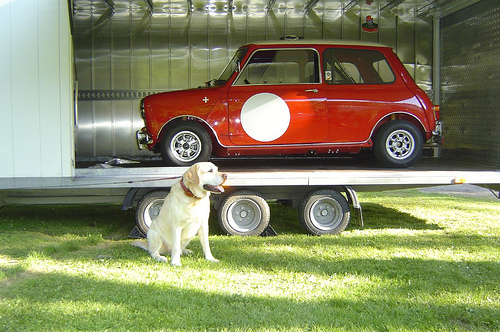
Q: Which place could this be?
A: It is a field.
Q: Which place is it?
A: It is a field.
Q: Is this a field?
A: Yes, it is a field.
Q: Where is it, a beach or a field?
A: It is a field.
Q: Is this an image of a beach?
A: No, the picture is showing a field.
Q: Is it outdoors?
A: Yes, it is outdoors.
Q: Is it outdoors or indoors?
A: It is outdoors.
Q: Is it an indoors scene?
A: No, it is outdoors.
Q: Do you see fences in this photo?
A: No, there are no fences.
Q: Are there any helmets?
A: No, there are no helmets.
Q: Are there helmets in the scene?
A: No, there are no helmets.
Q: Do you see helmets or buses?
A: No, there are no helmets or buses.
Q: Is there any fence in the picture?
A: No, there are no fences.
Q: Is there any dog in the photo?
A: Yes, there is a dog.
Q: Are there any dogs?
A: Yes, there is a dog.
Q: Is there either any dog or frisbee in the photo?
A: Yes, there is a dog.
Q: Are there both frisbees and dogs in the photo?
A: No, there is a dog but no frisbees.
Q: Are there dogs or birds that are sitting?
A: Yes, the dog is sitting.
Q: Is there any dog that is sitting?
A: Yes, there is a dog that is sitting.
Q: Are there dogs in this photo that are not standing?
A: Yes, there is a dog that is sitting.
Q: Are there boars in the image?
A: No, there are no boars.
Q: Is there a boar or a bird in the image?
A: No, there are no boars or birds.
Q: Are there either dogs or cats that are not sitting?
A: No, there is a dog but it is sitting.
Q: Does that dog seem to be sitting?
A: Yes, the dog is sitting.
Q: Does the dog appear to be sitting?
A: Yes, the dog is sitting.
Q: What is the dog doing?
A: The dog is sitting.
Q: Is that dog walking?
A: No, the dog is sitting.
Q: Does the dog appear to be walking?
A: No, the dog is sitting.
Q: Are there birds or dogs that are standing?
A: No, there is a dog but it is sitting.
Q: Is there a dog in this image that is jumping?
A: No, there is a dog but it is sitting.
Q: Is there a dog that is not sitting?
A: No, there is a dog but it is sitting.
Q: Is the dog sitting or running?
A: The dog is sitting.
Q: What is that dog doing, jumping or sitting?
A: The dog is sitting.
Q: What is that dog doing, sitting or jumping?
A: The dog is sitting.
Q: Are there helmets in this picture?
A: No, there are no helmets.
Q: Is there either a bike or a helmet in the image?
A: No, there are no helmets or bikes.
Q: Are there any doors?
A: Yes, there is a door.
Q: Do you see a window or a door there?
A: Yes, there is a door.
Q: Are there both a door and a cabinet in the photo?
A: No, there is a door but no cabinets.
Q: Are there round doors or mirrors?
A: Yes, there is a round door.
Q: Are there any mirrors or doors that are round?
A: Yes, the door is round.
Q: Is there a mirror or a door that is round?
A: Yes, the door is round.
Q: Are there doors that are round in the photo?
A: Yes, there is a round door.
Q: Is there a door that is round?
A: Yes, there is a door that is round.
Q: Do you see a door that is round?
A: Yes, there is a door that is round.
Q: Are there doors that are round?
A: Yes, there is a door that is round.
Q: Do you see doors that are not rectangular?
A: Yes, there is a round door.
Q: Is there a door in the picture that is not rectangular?
A: Yes, there is a round door.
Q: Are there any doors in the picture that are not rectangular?
A: Yes, there is a round door.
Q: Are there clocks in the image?
A: No, there are no clocks.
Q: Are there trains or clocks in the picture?
A: No, there are no clocks or trains.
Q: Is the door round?
A: Yes, the door is round.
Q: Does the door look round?
A: Yes, the door is round.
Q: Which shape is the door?
A: The door is round.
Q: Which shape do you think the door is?
A: The door is round.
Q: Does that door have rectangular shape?
A: No, the door is round.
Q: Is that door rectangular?
A: No, the door is round.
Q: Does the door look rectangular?
A: No, the door is round.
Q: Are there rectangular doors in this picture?
A: No, there is a door but it is round.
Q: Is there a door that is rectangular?
A: No, there is a door but it is round.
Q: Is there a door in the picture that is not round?
A: No, there is a door but it is round.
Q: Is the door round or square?
A: The door is round.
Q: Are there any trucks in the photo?
A: Yes, there is a truck.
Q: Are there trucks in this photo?
A: Yes, there is a truck.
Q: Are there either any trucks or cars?
A: Yes, there is a truck.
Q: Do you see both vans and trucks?
A: No, there is a truck but no vans.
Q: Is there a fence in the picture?
A: No, there are no fences.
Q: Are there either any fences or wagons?
A: No, there are no fences or wagons.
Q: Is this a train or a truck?
A: This is a truck.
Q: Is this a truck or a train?
A: This is a truck.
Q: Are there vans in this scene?
A: No, there are no vans.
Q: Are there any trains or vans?
A: No, there are no vans or trains.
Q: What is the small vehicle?
A: The vehicle is a car.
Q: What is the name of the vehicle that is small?
A: The vehicle is a car.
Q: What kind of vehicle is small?
A: The vehicle is a car.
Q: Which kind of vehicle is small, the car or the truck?
A: The car is small.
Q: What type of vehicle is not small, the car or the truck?
A: The truck is not small.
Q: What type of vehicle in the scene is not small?
A: The vehicle is a truck.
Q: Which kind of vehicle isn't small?
A: The vehicle is a truck.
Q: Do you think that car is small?
A: Yes, the car is small.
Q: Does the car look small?
A: Yes, the car is small.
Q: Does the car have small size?
A: Yes, the car is small.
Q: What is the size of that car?
A: The car is small.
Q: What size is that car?
A: The car is small.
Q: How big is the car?
A: The car is small.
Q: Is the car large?
A: No, the car is small.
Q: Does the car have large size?
A: No, the car is small.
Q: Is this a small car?
A: Yes, this is a small car.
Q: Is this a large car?
A: No, this is a small car.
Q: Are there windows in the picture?
A: Yes, there is a window.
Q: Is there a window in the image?
A: Yes, there is a window.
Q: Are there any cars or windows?
A: Yes, there is a window.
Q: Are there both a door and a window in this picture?
A: Yes, there are both a window and a door.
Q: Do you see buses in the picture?
A: No, there are no buses.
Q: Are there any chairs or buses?
A: No, there are no buses or chairs.